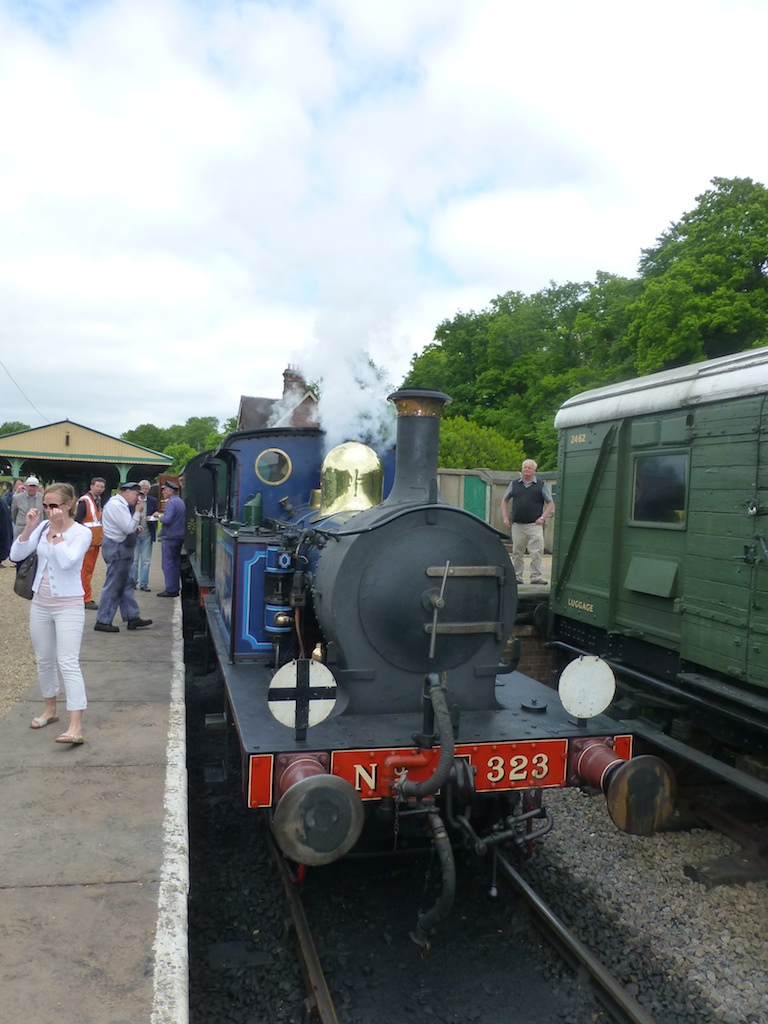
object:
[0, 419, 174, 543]
building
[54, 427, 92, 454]
wall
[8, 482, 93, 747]
woman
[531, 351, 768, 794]
train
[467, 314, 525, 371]
tree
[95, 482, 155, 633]
man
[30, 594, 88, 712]
pants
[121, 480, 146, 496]
hat